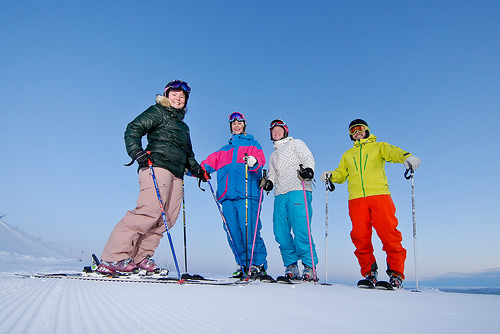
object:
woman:
[95, 78, 213, 277]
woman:
[184, 110, 270, 280]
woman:
[257, 117, 319, 281]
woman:
[318, 117, 423, 290]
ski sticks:
[322, 173, 331, 287]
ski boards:
[14, 271, 235, 285]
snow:
[0, 267, 500, 334]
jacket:
[261, 141, 311, 194]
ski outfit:
[199, 133, 268, 274]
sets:
[353, 277, 398, 290]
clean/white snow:
[0, 268, 499, 333]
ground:
[0, 271, 499, 333]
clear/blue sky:
[0, 0, 500, 288]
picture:
[3, 0, 500, 331]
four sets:
[146, 151, 420, 294]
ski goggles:
[348, 124, 371, 136]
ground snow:
[0, 277, 499, 332]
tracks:
[20, 277, 54, 333]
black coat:
[122, 94, 203, 179]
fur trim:
[153, 94, 173, 108]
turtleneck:
[272, 136, 294, 150]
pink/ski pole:
[297, 162, 318, 285]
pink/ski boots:
[95, 256, 144, 276]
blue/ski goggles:
[227, 111, 245, 123]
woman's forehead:
[231, 113, 245, 122]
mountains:
[426, 269, 472, 290]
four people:
[86, 79, 421, 289]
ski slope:
[0, 277, 500, 334]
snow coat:
[326, 133, 413, 203]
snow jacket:
[187, 130, 267, 202]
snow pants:
[267, 188, 319, 274]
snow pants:
[97, 167, 187, 265]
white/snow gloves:
[404, 155, 422, 171]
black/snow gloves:
[296, 166, 314, 181]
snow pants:
[345, 194, 407, 278]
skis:
[373, 279, 403, 290]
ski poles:
[409, 164, 419, 292]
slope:
[0, 216, 80, 263]